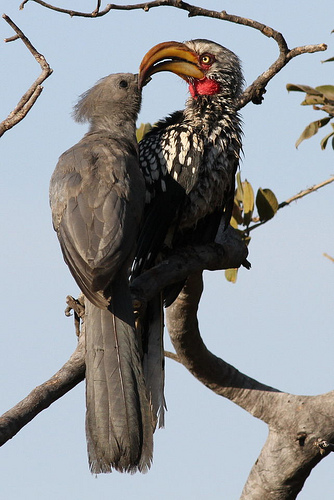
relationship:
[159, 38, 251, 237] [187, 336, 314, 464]
bird on branch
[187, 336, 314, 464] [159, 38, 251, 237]
branch with bird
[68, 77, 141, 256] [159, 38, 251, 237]
chick with bird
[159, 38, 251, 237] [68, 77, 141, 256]
bird with chick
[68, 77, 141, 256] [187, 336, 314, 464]
chick on branch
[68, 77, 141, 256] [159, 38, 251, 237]
chick hugging bird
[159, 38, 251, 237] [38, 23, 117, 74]
bird in sky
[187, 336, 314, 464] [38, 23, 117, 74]
branch in sky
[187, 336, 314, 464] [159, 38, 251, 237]
branch holding bird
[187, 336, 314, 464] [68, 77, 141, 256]
branch holding chick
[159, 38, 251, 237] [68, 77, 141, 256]
bird near chick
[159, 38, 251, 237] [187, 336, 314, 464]
bird sharing branch